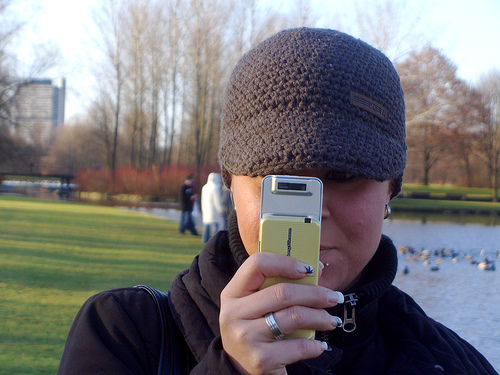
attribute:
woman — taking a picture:
[57, 27, 498, 374]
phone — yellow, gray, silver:
[258, 172, 326, 343]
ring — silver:
[263, 311, 286, 339]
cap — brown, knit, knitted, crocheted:
[217, 26, 408, 197]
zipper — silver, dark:
[338, 289, 360, 333]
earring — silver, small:
[383, 202, 395, 221]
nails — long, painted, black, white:
[296, 256, 346, 353]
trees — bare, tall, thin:
[82, 1, 227, 189]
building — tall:
[8, 75, 68, 145]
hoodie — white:
[201, 169, 226, 226]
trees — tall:
[397, 48, 499, 194]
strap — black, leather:
[132, 278, 191, 374]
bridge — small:
[3, 169, 77, 190]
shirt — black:
[180, 186, 197, 212]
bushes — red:
[79, 167, 201, 197]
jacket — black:
[61, 229, 497, 374]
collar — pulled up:
[169, 229, 399, 353]